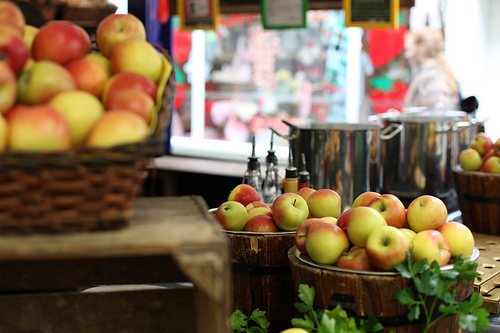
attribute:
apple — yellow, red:
[216, 200, 252, 235]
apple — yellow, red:
[308, 221, 350, 263]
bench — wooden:
[1, 188, 243, 330]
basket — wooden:
[449, 162, 499, 237]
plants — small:
[239, 250, 481, 331]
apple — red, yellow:
[271, 191, 308, 228]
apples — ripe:
[0, 28, 166, 143]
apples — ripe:
[207, 177, 340, 231]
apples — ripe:
[467, 130, 499, 166]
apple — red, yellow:
[413, 228, 451, 267]